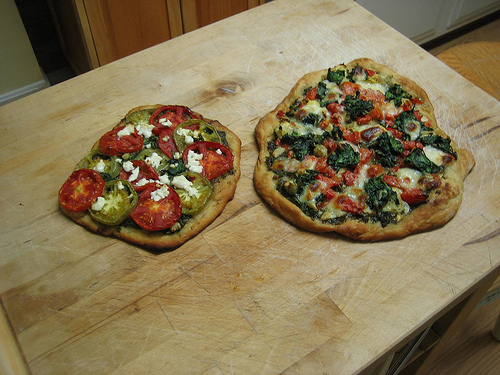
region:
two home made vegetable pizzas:
[57, 57, 476, 253]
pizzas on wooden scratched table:
[0, 0, 499, 373]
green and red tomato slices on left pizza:
[56, 101, 231, 231]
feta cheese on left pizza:
[90, 116, 221, 208]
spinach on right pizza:
[262, 66, 457, 226]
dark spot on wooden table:
[196, 75, 251, 107]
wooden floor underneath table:
[415, 16, 498, 372]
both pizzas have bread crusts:
[56, 56, 474, 252]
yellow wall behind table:
[0, 0, 45, 95]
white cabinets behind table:
[353, 0, 498, 45]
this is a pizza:
[251, 59, 440, 236]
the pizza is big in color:
[249, 63, 438, 243]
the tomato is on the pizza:
[141, 189, 180, 220]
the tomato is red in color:
[138, 198, 170, 226]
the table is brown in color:
[8, 277, 337, 372]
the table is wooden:
[23, 258, 293, 373]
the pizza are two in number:
[49, 60, 466, 277]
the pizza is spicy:
[284, 99, 411, 204]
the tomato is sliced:
[141, 190, 173, 220]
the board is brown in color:
[87, 4, 159, 44]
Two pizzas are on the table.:
[37, 47, 484, 281]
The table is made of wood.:
[0, 238, 460, 373]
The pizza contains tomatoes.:
[52, 89, 241, 261]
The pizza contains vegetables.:
[247, 57, 472, 251]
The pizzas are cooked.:
[44, 36, 486, 273]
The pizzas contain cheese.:
[41, 55, 489, 282]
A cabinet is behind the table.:
[71, 0, 276, 82]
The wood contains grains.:
[0, 243, 409, 373]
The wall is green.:
[0, 0, 51, 115]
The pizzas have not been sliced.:
[40, 44, 486, 274]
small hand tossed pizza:
[44, 93, 249, 255]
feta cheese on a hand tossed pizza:
[72, 129, 201, 211]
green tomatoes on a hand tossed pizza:
[61, 104, 211, 241]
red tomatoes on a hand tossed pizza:
[64, 128, 229, 232]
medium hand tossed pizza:
[253, 83, 449, 270]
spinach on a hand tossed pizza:
[228, 92, 454, 238]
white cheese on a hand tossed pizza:
[269, 73, 427, 238]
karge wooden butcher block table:
[16, 53, 451, 347]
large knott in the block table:
[153, 44, 300, 116]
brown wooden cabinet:
[33, 3, 230, 60]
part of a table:
[277, 300, 360, 354]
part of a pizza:
[317, 154, 367, 210]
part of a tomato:
[151, 205, 168, 220]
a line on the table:
[161, 310, 179, 338]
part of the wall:
[0, 57, 33, 84]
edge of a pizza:
[345, 229, 377, 243]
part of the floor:
[465, 345, 485, 367]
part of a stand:
[441, 315, 451, 341]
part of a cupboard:
[406, 8, 445, 37]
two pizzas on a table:
[56, 53, 461, 233]